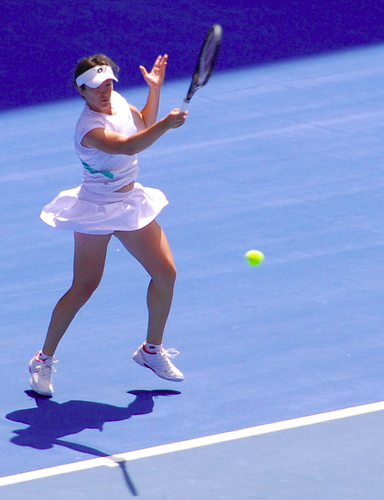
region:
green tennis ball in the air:
[236, 233, 301, 282]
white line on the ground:
[225, 383, 301, 471]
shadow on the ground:
[44, 387, 130, 469]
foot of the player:
[131, 327, 195, 391]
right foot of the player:
[6, 339, 74, 409]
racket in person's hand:
[183, 13, 238, 92]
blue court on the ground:
[233, 342, 299, 390]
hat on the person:
[63, 42, 125, 106]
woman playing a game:
[15, 38, 237, 285]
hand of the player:
[135, 46, 180, 99]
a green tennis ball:
[237, 244, 273, 273]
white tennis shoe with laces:
[131, 340, 193, 384]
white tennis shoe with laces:
[26, 343, 55, 404]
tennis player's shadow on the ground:
[5, 388, 173, 497]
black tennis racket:
[171, 25, 241, 119]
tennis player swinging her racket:
[28, 18, 196, 403]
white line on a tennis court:
[3, 391, 383, 493]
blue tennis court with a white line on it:
[187, 59, 382, 498]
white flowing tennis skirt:
[35, 177, 172, 240]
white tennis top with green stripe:
[57, 96, 163, 193]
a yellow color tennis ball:
[221, 242, 270, 269]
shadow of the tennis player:
[16, 389, 141, 471]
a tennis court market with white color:
[78, 387, 364, 469]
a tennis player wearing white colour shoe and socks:
[130, 336, 193, 385]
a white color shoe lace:
[162, 349, 180, 359]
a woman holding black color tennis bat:
[170, 18, 228, 140]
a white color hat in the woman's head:
[71, 63, 123, 87]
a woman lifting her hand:
[137, 53, 172, 116]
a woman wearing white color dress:
[60, 104, 166, 230]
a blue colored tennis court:
[256, 57, 351, 211]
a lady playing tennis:
[72, 24, 210, 303]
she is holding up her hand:
[58, 19, 172, 122]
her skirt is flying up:
[36, 178, 181, 253]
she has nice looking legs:
[37, 223, 181, 355]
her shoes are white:
[18, 331, 197, 410]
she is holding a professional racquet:
[175, 29, 238, 148]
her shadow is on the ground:
[1, 383, 181, 493]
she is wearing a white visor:
[61, 54, 121, 111]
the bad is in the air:
[195, 226, 289, 283]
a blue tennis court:
[33, 95, 341, 294]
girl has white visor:
[71, 54, 113, 88]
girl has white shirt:
[68, 99, 151, 213]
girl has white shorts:
[46, 187, 165, 251]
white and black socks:
[117, 329, 186, 361]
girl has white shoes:
[107, 346, 205, 378]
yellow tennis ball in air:
[237, 246, 286, 297]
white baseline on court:
[37, 380, 380, 499]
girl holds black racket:
[177, 30, 229, 102]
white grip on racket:
[179, 96, 194, 130]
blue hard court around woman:
[215, 137, 373, 400]